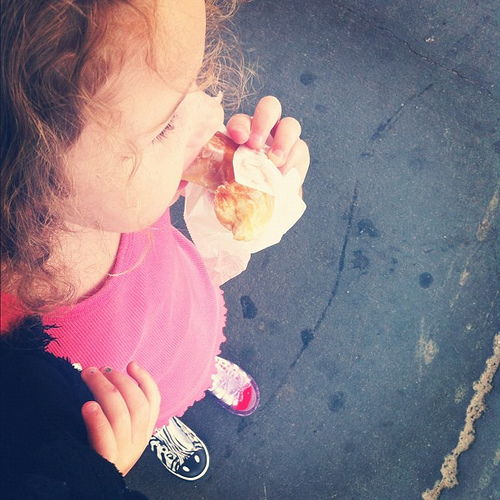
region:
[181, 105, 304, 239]
Glazed donut in girl's hand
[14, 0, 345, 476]
A young girl eating a donut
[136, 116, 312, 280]
White wrapper around donut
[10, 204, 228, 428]
Pink shirt on the girl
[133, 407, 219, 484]
Black show on girl's right foot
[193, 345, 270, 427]
Pink shoe on girl's left foot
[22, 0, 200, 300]
Short brown hair on the girl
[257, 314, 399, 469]
Concrete beneath the girl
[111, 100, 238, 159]
The girl's eyes are closed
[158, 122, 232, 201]
The girl's mouth is open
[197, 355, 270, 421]
a pink shoe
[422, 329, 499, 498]
a crack in the ground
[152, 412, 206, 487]
a black and white shoe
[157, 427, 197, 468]
a zebra print shoe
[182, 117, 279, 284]
the girl eating a doughnut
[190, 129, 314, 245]
the doughnut in her hand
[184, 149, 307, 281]
the wax paper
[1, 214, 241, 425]
the pink tank top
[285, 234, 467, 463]
spots on the ground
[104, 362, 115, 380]
paint on her finger nail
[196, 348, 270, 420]
a red shoe worn by a little girl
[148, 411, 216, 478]
a black show worn by a little girl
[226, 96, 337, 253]
the hand of a girl holding something to eat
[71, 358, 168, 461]
the hand and fingers of a little girl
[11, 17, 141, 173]
curly hair on a little girl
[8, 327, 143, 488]
a black stuffed toy being held by a little girl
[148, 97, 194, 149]
the eye of a little girl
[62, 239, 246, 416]
a lavender top worn by a little girl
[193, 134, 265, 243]
a donut being eaten by a little girl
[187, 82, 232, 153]
the nose of a little girl eating something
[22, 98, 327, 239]
A young girl eating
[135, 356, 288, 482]
Two different color shoes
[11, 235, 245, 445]
Pink shirt on a young girl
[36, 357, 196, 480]
Right hand of young girl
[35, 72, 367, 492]
A young girl standing on black top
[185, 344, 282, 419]
A pink and white shoe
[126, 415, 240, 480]
A black and white shoe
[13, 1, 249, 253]
Face of a young girl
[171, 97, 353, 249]
Left hand of a young girl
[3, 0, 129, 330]
Brown curly hair of a young girl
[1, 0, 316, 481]
dark haired little girl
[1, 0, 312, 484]
dark haired little girl with pink shirt on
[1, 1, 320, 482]
dark haired little girl eating donut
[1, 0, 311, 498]
dark haired little girl holding black teddy bear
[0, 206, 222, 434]
little girls pink tank top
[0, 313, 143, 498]
little girls black teddy bear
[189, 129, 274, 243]
donut the little girl is eating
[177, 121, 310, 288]
donut wrapper in the little girls hand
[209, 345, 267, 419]
little girl pink shoe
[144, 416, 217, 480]
little girls black shoe